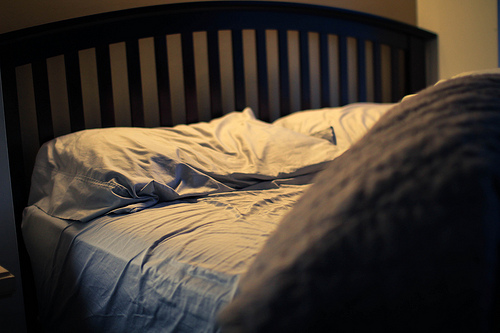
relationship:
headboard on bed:
[0, 0, 437, 232] [2, 2, 468, 332]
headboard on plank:
[0, 0, 437, 232] [148, 33, 176, 128]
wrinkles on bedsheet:
[98, 128, 306, 262] [21, 169, 319, 330]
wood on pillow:
[201, 20, 293, 111] [34, 95, 345, 210]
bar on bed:
[206, 25, 226, 126] [2, 2, 468, 332]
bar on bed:
[148, 33, 178, 126] [2, 2, 468, 332]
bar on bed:
[178, 27, 202, 119] [2, 2, 468, 332]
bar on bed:
[293, 33, 315, 111] [2, 2, 468, 332]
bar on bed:
[125, 34, 148, 125] [2, 2, 468, 332]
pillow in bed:
[31, 106, 341, 226] [2, 2, 468, 332]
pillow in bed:
[272, 104, 401, 178] [2, 2, 468, 332]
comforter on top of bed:
[208, 72, 498, 331] [2, 2, 468, 332]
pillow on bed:
[272, 104, 401, 178] [2, 2, 468, 332]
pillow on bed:
[36, 106, 342, 226] [2, 2, 468, 332]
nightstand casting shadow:
[0, 260, 18, 330] [22, 243, 88, 330]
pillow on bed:
[271, 98, 402, 178] [37, 133, 439, 315]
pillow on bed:
[36, 106, 342, 226] [37, 133, 439, 315]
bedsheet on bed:
[26, 170, 316, 330] [2, 2, 468, 332]